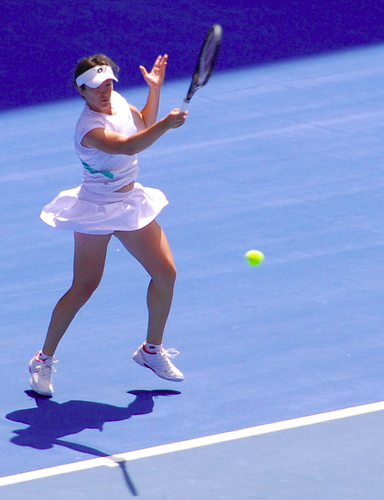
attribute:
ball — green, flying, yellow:
[244, 249, 265, 267]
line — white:
[0, 400, 382, 488]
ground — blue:
[2, 45, 382, 498]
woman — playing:
[27, 51, 186, 399]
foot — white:
[28, 350, 55, 401]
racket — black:
[178, 22, 224, 115]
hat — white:
[73, 64, 119, 90]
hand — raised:
[164, 107, 189, 131]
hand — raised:
[136, 53, 170, 91]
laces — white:
[155, 344, 181, 370]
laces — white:
[34, 360, 55, 387]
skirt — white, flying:
[38, 184, 169, 235]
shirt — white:
[70, 89, 135, 193]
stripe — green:
[78, 157, 113, 183]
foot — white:
[131, 342, 184, 383]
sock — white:
[36, 348, 56, 367]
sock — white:
[144, 341, 166, 353]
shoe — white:
[29, 353, 57, 399]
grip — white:
[177, 97, 191, 116]